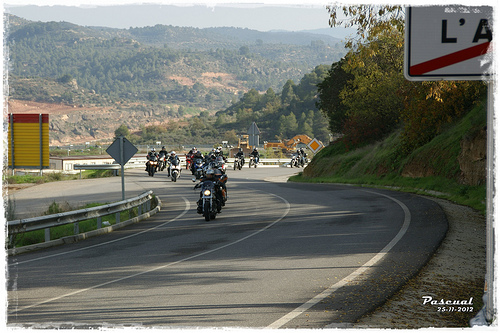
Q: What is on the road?
A: Bikes.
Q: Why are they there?
A: Traveling.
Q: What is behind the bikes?
A: Hills.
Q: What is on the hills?
A: Trees.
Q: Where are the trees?
A: On the hills.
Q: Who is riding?
A: People.